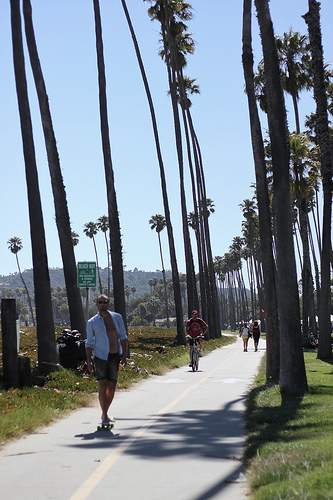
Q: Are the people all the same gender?
A: No, they are both male and female.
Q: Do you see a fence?
A: No, there are no fences.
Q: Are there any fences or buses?
A: No, there are no fences or buses.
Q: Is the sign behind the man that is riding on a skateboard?
A: Yes, the sign is behind the man.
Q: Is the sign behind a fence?
A: No, the sign is behind the man.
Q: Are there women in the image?
A: Yes, there is a woman.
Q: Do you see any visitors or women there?
A: Yes, there is a woman.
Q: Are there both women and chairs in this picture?
A: No, there is a woman but no chairs.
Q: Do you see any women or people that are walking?
A: Yes, the woman is walking.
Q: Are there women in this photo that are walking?
A: Yes, there is a woman that is walking.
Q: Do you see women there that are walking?
A: Yes, there is a woman that is walking.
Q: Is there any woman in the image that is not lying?
A: Yes, there is a woman that is walking.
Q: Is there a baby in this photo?
A: No, there are no babies.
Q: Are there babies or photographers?
A: No, there are no babies or photographers.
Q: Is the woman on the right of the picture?
A: Yes, the woman is on the right of the image.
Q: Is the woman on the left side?
A: No, the woman is on the right of the image.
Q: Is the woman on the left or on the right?
A: The woman is on the right of the image.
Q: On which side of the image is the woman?
A: The woman is on the right of the image.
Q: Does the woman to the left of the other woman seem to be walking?
A: Yes, the woman is walking.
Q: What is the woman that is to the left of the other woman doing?
A: The woman is walking.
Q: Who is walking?
A: The woman is walking.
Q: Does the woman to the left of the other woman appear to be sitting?
A: No, the woman is walking.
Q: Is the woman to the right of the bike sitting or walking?
A: The woman is walking.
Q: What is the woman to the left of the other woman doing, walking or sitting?
A: The woman is walking.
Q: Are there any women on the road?
A: Yes, there is a woman on the road.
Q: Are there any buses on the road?
A: No, there is a woman on the road.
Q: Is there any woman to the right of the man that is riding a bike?
A: Yes, there is a woman to the right of the man.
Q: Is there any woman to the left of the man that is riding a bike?
A: No, the woman is to the right of the man.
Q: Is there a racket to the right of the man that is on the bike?
A: No, there is a woman to the right of the man.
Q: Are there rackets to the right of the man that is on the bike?
A: No, there is a woman to the right of the man.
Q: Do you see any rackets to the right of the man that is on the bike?
A: No, there is a woman to the right of the man.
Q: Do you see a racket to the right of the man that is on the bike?
A: No, there is a woman to the right of the man.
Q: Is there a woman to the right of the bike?
A: Yes, there is a woman to the right of the bike.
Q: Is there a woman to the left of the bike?
A: No, the woman is to the right of the bike.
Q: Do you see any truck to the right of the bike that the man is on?
A: No, there is a woman to the right of the bike.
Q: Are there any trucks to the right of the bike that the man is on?
A: No, there is a woman to the right of the bike.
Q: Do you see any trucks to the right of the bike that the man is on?
A: No, there is a woman to the right of the bike.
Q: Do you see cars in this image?
A: No, there are no cars.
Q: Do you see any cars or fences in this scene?
A: No, there are no cars or fences.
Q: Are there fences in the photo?
A: No, there are no fences.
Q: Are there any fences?
A: No, there are no fences.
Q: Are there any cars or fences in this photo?
A: No, there are no fences or cars.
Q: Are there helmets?
A: No, there are no helmets.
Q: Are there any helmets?
A: No, there are no helmets.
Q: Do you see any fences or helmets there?
A: No, there are no helmets or fences.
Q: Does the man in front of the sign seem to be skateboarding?
A: Yes, the man is skateboarding.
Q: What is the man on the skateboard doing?
A: The man is skateboarding.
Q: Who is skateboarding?
A: The man is skateboarding.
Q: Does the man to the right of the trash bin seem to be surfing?
A: No, the man is skateboarding.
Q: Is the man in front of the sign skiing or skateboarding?
A: The man is skateboarding.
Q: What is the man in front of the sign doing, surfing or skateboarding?
A: The man is skateboarding.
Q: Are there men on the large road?
A: Yes, there is a man on the road.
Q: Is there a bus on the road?
A: No, there is a man on the road.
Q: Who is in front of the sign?
A: The man is in front of the sign.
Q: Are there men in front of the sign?
A: Yes, there is a man in front of the sign.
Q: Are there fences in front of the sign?
A: No, there is a man in front of the sign.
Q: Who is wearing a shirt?
A: The man is wearing a shirt.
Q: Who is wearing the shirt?
A: The man is wearing a shirt.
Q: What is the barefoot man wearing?
A: The man is wearing a shirt.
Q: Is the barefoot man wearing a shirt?
A: Yes, the man is wearing a shirt.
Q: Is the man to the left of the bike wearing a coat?
A: No, the man is wearing a shirt.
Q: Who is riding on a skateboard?
A: The man is riding on a skateboard.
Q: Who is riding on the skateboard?
A: The man is riding on a skateboard.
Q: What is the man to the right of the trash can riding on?
A: The man is riding on a skateboard.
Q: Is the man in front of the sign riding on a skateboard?
A: Yes, the man is riding on a skateboard.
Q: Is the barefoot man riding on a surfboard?
A: No, the man is riding on a skateboard.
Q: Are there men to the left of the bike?
A: Yes, there is a man to the left of the bike.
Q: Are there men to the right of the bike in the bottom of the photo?
A: No, the man is to the left of the bike.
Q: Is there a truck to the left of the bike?
A: No, there is a man to the left of the bike.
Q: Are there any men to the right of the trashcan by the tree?
A: Yes, there is a man to the right of the garbage can.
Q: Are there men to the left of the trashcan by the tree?
A: No, the man is to the right of the garbage bin.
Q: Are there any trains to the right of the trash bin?
A: No, there is a man to the right of the trash bin.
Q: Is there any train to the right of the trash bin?
A: No, there is a man to the right of the trash bin.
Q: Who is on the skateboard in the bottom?
A: The man is on the skateboard.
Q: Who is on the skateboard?
A: The man is on the skateboard.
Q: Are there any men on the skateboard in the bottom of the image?
A: Yes, there is a man on the skateboard.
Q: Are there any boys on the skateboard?
A: No, there is a man on the skateboard.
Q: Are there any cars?
A: No, there are no cars.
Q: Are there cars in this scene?
A: No, there are no cars.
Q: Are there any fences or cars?
A: No, there are no cars or fences.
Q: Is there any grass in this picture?
A: Yes, there is grass.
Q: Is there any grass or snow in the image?
A: Yes, there is grass.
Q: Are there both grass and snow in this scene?
A: No, there is grass but no snow.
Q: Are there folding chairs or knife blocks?
A: No, there are no folding chairs or knife blocks.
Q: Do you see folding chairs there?
A: No, there are no folding chairs.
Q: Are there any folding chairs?
A: No, there are no folding chairs.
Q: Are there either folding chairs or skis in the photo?
A: No, there are no folding chairs or skis.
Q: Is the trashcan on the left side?
A: Yes, the trashcan is on the left of the image.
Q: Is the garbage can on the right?
A: No, the garbage can is on the left of the image.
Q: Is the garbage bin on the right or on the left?
A: The garbage bin is on the left of the image.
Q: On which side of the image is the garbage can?
A: The garbage can is on the left of the image.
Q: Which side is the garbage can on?
A: The garbage can is on the left of the image.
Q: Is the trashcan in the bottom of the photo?
A: Yes, the trashcan is in the bottom of the image.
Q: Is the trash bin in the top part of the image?
A: No, the trash bin is in the bottom of the image.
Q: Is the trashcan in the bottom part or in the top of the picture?
A: The trashcan is in the bottom of the image.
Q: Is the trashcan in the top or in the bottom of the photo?
A: The trashcan is in the bottom of the image.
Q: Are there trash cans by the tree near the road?
A: Yes, there is a trash can by the tree.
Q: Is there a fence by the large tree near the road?
A: No, there is a trash can by the tree.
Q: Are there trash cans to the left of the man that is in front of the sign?
A: Yes, there is a trash can to the left of the man.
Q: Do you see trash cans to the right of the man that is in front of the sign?
A: No, the trash can is to the left of the man.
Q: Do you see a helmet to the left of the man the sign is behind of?
A: No, there is a trash can to the left of the man.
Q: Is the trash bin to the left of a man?
A: Yes, the trash bin is to the left of a man.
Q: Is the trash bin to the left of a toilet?
A: No, the trash bin is to the left of a man.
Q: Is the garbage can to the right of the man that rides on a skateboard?
A: No, the garbage can is to the left of the man.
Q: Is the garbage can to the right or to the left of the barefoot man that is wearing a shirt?
A: The garbage can is to the left of the man.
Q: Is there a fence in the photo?
A: No, there are no fences.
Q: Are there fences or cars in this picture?
A: No, there are no fences or cars.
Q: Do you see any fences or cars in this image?
A: No, there are no fences or cars.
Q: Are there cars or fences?
A: No, there are no fences or cars.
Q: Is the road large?
A: Yes, the road is large.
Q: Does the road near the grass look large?
A: Yes, the road is large.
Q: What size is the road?
A: The road is large.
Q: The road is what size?
A: The road is large.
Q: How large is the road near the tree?
A: The road is large.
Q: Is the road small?
A: No, the road is large.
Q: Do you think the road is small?
A: No, the road is large.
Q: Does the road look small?
A: No, the road is large.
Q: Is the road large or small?
A: The road is large.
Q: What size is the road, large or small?
A: The road is large.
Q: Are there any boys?
A: No, there are no boys.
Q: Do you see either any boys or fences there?
A: No, there are no boys or fences.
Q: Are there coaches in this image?
A: No, there are no coaches.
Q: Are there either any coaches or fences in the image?
A: No, there are no coaches or fences.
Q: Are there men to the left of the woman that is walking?
A: Yes, there is a man to the left of the woman.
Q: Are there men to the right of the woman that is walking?
A: No, the man is to the left of the woman.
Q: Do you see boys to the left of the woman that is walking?
A: No, there is a man to the left of the woman.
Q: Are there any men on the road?
A: Yes, there is a man on the road.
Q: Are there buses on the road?
A: No, there is a man on the road.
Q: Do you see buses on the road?
A: No, there is a man on the road.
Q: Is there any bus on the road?
A: No, there is a man on the road.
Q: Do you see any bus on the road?
A: No, there is a man on the road.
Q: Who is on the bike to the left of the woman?
A: The man is on the bike.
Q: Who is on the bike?
A: The man is on the bike.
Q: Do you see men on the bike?
A: Yes, there is a man on the bike.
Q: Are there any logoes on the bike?
A: No, there is a man on the bike.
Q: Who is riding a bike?
A: The man is riding a bike.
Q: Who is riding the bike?
A: The man is riding a bike.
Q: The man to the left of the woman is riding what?
A: The man is riding a bike.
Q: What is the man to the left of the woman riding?
A: The man is riding a bike.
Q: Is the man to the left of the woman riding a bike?
A: Yes, the man is riding a bike.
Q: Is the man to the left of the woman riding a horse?
A: No, the man is riding a bike.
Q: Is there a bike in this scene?
A: Yes, there is a bike.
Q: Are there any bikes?
A: Yes, there is a bike.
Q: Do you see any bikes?
A: Yes, there is a bike.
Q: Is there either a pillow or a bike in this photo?
A: Yes, there is a bike.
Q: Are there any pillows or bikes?
A: Yes, there is a bike.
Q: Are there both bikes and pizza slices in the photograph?
A: No, there is a bike but no pizza slices.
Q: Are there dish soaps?
A: No, there are no dish soaps.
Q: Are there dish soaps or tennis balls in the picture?
A: No, there are no dish soaps or tennis balls.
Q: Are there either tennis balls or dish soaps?
A: No, there are no dish soaps or tennis balls.